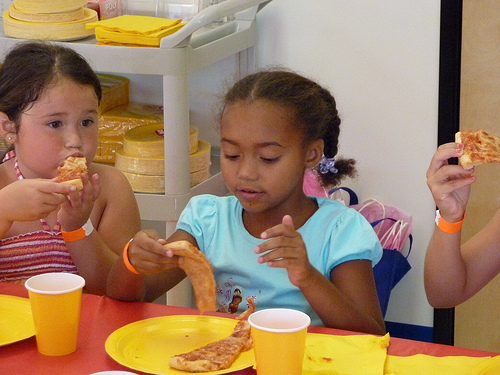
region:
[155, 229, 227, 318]
girl holding slice of pizza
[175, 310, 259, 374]
slice of pizza sitting on plate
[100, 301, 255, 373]
pizza on a plate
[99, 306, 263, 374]
plate holding pizza is yellow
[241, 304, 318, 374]
yellow cup next to plate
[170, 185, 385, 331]
girl wearing blue shirt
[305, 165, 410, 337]
gift bags behind girl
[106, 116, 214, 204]
stack of plates on shelf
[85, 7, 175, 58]
stack of napkins on shelf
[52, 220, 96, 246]
girl wearing orange wrist band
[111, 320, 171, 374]
The plate is yellow.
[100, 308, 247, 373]
A piece of pizza is on the plate.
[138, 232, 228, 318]
A girl is holding a piece of pizza.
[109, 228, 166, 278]
The girl is wearing an orange bracelet.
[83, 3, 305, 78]
Napkins are on a cart.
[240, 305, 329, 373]
The cup is yellow and white.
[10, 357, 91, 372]
The table is red.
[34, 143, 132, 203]
A girl is eating pizza.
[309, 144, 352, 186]
The girl's hair tie is purple.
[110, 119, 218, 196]
Yellow paper plates stacked on a cart.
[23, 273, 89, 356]
orange and white cup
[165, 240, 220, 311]
slice of cheese pizza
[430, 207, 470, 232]
bright orange and white bracelet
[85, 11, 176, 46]
stack of orange, square napkins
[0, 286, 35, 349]
round and orange plate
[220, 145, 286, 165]
eyes looking down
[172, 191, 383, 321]
short sleeve blue shirt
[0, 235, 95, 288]
orange, white and red shirt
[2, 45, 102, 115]
short dark brown hair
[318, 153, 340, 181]
blue pony tail holder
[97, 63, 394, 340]
A LITTLE GIRL HOLDING A SLICE OF PIZZA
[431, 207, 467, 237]
AN ORANGE WRIST BAND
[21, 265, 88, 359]
A YELLOW CUP ON THE TABLE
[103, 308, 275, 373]
A SLICE OF PIZZA ON A PLATE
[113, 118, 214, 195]
A STACK OF YELLOW PLATES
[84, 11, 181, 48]
A STACK OF YELLOW NAPKINS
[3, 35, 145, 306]
A LITTLE GIRL EATING A SLICE OF PIZZA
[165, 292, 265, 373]
A SLICE OF CHEESE PIZZA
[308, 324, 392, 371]
A YELLOW NAPKIN ON THE TABLE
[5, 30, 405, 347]
A PICTURE OF TWO LITTLE GIRLS HAVING PIZZA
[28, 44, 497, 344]
Kids are eating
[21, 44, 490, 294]
the kids are eating pizza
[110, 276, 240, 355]
the plates are round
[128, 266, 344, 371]
the plates are yellow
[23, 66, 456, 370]
the child is holding a slice of pizza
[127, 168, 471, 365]
the children are sitting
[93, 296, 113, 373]
the tablecloth is red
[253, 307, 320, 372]
the cups are yellow and white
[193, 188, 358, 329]
a girl is wearing a blue shirt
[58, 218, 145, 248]
a girl is wearing an orange band around her wrist